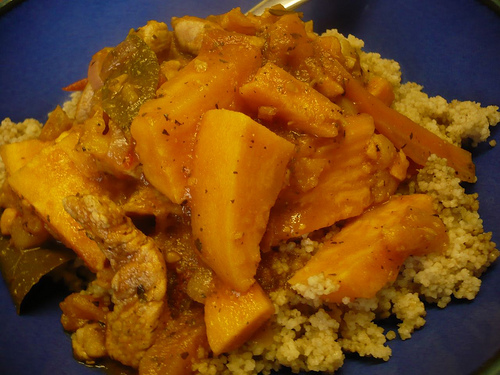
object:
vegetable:
[183, 259, 284, 349]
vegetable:
[8, 145, 167, 313]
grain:
[225, 158, 248, 187]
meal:
[0, 0, 500, 375]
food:
[0, 0, 500, 375]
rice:
[285, 273, 342, 306]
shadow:
[22, 281, 72, 319]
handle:
[242, 0, 313, 14]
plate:
[0, 0, 500, 375]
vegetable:
[273, 189, 442, 309]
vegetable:
[263, 111, 394, 251]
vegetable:
[238, 63, 345, 146]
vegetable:
[184, 109, 284, 296]